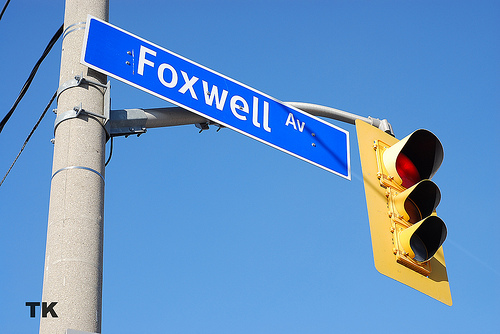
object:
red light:
[380, 127, 445, 190]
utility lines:
[0, 0, 63, 184]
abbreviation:
[284, 112, 306, 133]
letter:
[136, 42, 158, 79]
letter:
[154, 61, 180, 89]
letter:
[177, 70, 199, 101]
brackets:
[49, 75, 111, 144]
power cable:
[0, 87, 60, 184]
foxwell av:
[78, 13, 351, 183]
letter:
[199, 78, 271, 132]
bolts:
[124, 49, 131, 65]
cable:
[0, 21, 61, 131]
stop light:
[351, 116, 451, 306]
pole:
[98, 100, 395, 141]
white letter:
[261, 97, 273, 136]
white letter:
[227, 93, 249, 120]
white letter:
[201, 77, 231, 110]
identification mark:
[21, 299, 51, 320]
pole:
[35, 0, 108, 333]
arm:
[108, 101, 394, 138]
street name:
[75, 17, 356, 183]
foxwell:
[137, 44, 271, 134]